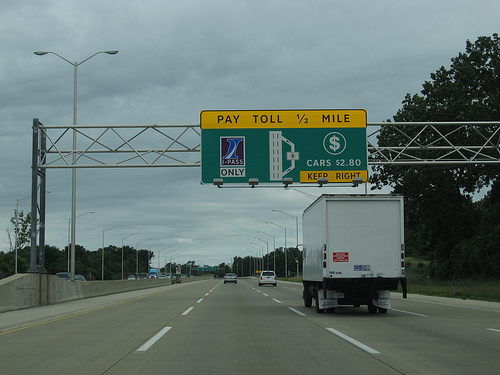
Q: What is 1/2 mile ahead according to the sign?
A: Pay toll.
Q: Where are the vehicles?
A: The highway.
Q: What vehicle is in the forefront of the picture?
A: A truck.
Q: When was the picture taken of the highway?
A: Daytime.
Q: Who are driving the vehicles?
A: People.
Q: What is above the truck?
A: A sign.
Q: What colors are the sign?
A: Green, white, and yellow.